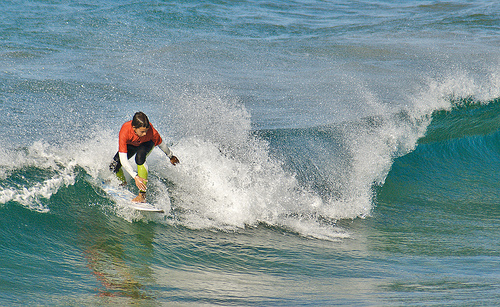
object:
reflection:
[80, 208, 156, 306]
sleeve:
[156, 140, 174, 161]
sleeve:
[114, 150, 137, 182]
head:
[129, 110, 150, 139]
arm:
[116, 129, 140, 181]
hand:
[167, 153, 179, 168]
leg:
[131, 139, 151, 195]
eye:
[140, 130, 148, 135]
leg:
[108, 148, 129, 191]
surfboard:
[103, 186, 163, 215]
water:
[0, 0, 499, 305]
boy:
[109, 110, 179, 203]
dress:
[116, 119, 163, 156]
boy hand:
[132, 176, 151, 195]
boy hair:
[128, 110, 151, 129]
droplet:
[79, 83, 85, 90]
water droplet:
[246, 145, 256, 152]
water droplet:
[246, 99, 256, 106]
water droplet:
[17, 99, 27, 104]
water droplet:
[109, 85, 117, 91]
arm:
[150, 126, 174, 158]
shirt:
[115, 120, 162, 155]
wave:
[0, 24, 499, 243]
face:
[135, 126, 150, 137]